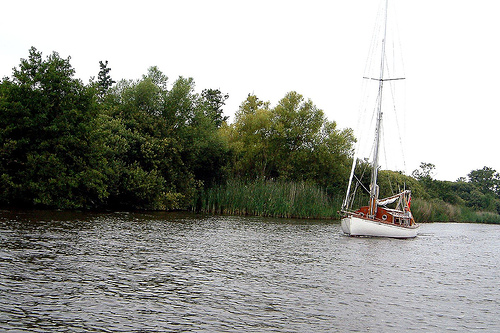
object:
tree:
[30, 63, 85, 216]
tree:
[83, 79, 133, 209]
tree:
[117, 78, 178, 210]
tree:
[182, 85, 233, 214]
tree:
[238, 97, 276, 184]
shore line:
[2, 196, 498, 223]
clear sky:
[1, 4, 498, 186]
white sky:
[3, 1, 498, 183]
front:
[338, 209, 378, 237]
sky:
[209, 31, 367, 77]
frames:
[361, 205, 402, 222]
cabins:
[357, 200, 413, 225]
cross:
[360, 3, 405, 183]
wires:
[364, 0, 386, 215]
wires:
[346, 137, 362, 211]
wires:
[387, 13, 405, 208]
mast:
[368, 0, 387, 219]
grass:
[256, 180, 321, 217]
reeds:
[453, 206, 470, 222]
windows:
[380, 216, 385, 220]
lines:
[381, 80, 405, 194]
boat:
[336, 0, 420, 238]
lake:
[60, 246, 375, 313]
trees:
[225, 95, 285, 176]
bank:
[233, 204, 315, 225]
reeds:
[210, 188, 235, 216]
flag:
[403, 193, 412, 215]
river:
[0, 210, 498, 329]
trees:
[411, 163, 441, 194]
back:
[390, 187, 423, 237]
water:
[0, 213, 498, 330]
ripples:
[1, 217, 255, 331]